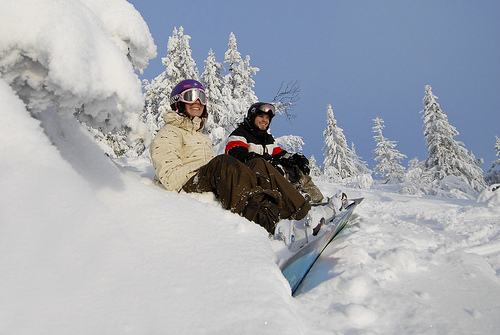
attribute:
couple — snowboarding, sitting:
[149, 80, 349, 250]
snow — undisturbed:
[1, 81, 497, 333]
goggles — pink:
[168, 87, 208, 107]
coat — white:
[150, 111, 217, 192]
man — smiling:
[225, 100, 351, 213]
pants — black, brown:
[182, 152, 312, 235]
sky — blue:
[126, 0, 499, 180]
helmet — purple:
[169, 79, 206, 110]